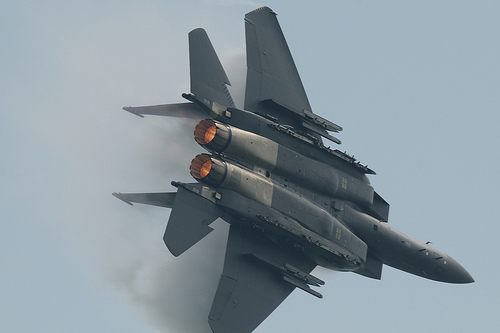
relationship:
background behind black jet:
[24, 23, 115, 317] [106, 9, 485, 331]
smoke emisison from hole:
[148, 114, 202, 181] [174, 147, 224, 172]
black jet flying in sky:
[109, 7, 475, 333] [2, 0, 482, 327]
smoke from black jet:
[121, 249, 223, 331] [109, 7, 475, 333]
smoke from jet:
[93, 32, 210, 328] [113, 3, 475, 330]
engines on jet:
[171, 121, 238, 196] [140, 50, 385, 320]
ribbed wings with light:
[122, 7, 364, 158] [185, 118, 220, 178]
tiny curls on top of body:
[421, 237, 445, 264] [417, 238, 443, 260]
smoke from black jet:
[121, 249, 213, 333] [109, 7, 475, 333]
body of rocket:
[363, 212, 478, 284] [297, 200, 473, 285]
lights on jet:
[188, 115, 236, 190] [158, 119, 259, 182]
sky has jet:
[2, 0, 482, 327] [113, 3, 475, 330]